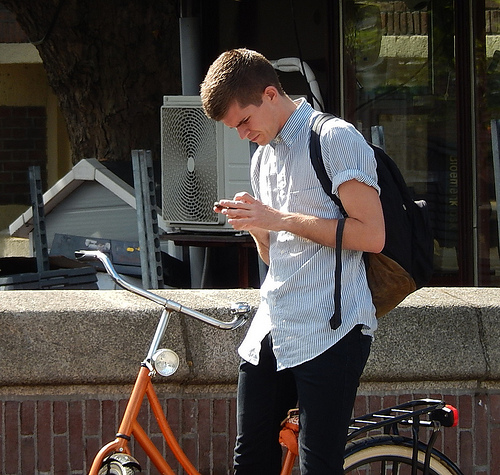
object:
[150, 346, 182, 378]
bicycle headlight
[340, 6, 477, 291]
reflections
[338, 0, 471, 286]
glass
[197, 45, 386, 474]
man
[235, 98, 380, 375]
shirt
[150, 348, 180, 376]
front light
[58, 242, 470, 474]
bicycle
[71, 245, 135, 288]
right handlebar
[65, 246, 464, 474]
bike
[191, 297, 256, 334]
left handlebar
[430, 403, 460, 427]
back reflector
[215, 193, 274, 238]
left hand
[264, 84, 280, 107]
left ear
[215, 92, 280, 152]
man's face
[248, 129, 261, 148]
mouth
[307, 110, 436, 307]
black bookbag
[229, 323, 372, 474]
black pants